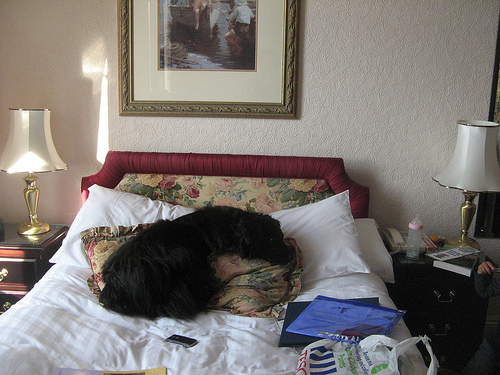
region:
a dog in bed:
[91, 142, 328, 324]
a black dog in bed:
[67, 200, 375, 349]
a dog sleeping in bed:
[80, 192, 365, 324]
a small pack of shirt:
[280, 264, 422, 360]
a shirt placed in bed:
[267, 281, 411, 363]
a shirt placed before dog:
[266, 283, 373, 358]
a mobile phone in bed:
[143, 310, 239, 372]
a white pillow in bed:
[263, 185, 371, 292]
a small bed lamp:
[7, 100, 84, 247]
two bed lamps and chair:
[21, 97, 498, 217]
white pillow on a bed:
[38, 192, 135, 279]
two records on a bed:
[274, 286, 406, 361]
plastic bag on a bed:
[294, 332, 428, 373]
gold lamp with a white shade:
[425, 92, 497, 263]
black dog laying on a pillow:
[84, 188, 306, 349]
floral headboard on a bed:
[91, 139, 361, 213]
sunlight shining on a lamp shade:
[17, 105, 72, 192]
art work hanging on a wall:
[110, 16, 312, 134]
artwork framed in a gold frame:
[148, 3, 270, 104]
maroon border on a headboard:
[150, 149, 247, 179]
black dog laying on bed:
[88, 146, 319, 373]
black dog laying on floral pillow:
[87, 178, 294, 373]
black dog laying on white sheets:
[78, 184, 324, 374]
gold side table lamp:
[430, 116, 499, 243]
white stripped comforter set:
[20, 288, 95, 369]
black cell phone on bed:
[161, 328, 205, 349]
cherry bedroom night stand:
[0, 226, 65, 298]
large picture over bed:
[107, 0, 319, 125]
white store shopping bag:
[293, 334, 460, 374]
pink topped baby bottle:
[401, 211, 428, 261]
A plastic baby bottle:
[407, 213, 423, 260]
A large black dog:
[97, 201, 286, 321]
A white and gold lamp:
[0, 104, 71, 236]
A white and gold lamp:
[430, 116, 497, 251]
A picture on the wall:
[115, 0, 301, 122]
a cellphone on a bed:
[165, 330, 201, 348]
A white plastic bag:
[293, 335, 440, 374]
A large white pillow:
[51, 182, 194, 264]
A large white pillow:
[270, 190, 370, 275]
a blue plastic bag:
[282, 292, 406, 344]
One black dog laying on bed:
[80, 183, 305, 315]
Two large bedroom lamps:
[8, 108, 488, 258]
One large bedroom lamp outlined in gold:
[0, 106, 69, 256]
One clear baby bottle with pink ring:
[402, 214, 433, 265]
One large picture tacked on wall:
[114, 3, 301, 125]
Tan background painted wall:
[330, 22, 421, 113]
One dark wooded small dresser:
[398, 255, 489, 351]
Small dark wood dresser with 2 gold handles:
[394, 268, 496, 358]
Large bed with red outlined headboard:
[69, 140, 382, 232]